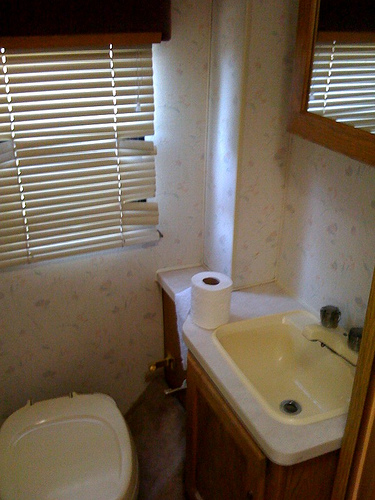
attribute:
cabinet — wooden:
[183, 348, 374, 498]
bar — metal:
[147, 346, 189, 398]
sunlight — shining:
[55, 62, 198, 226]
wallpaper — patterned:
[4, 282, 136, 378]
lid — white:
[7, 372, 149, 498]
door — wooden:
[171, 353, 268, 495]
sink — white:
[194, 317, 364, 445]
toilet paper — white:
[171, 268, 234, 333]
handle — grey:
[317, 304, 344, 328]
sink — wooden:
[177, 292, 350, 496]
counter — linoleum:
[154, 260, 366, 467]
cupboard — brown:
[183, 352, 343, 498]